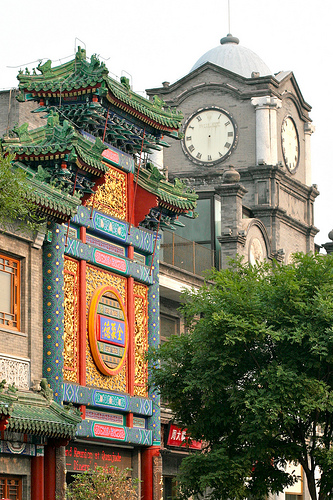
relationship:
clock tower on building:
[143, 30, 311, 277] [146, 30, 320, 497]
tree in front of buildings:
[143, 247, 333, 498] [0, 30, 333, 498]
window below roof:
[1, 252, 23, 330] [1, 44, 199, 230]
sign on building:
[86, 281, 130, 377] [0, 45, 199, 499]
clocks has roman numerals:
[178, 101, 242, 175] [187, 112, 234, 162]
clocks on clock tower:
[183, 105, 301, 175] [143, 30, 311, 277]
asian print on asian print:
[172, 427, 187, 441] [167, 425, 206, 448]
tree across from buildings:
[143, 247, 333, 498] [0, 30, 333, 498]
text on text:
[64, 446, 124, 471] [64, 444, 124, 471]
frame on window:
[1, 255, 18, 329] [1, 252, 23, 330]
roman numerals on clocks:
[187, 112, 234, 162] [178, 101, 242, 175]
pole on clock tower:
[228, 1, 232, 38] [143, 30, 311, 277]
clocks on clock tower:
[178, 101, 242, 175] [143, 30, 311, 277]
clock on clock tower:
[281, 110, 301, 173] [143, 30, 311, 277]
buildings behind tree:
[0, 30, 333, 498] [143, 247, 333, 498]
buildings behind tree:
[0, 30, 333, 498] [64, 463, 138, 499]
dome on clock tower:
[196, 44, 261, 78] [143, 30, 311, 277]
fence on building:
[163, 229, 216, 278] [146, 30, 320, 497]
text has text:
[64, 444, 124, 471] [64, 446, 124, 471]